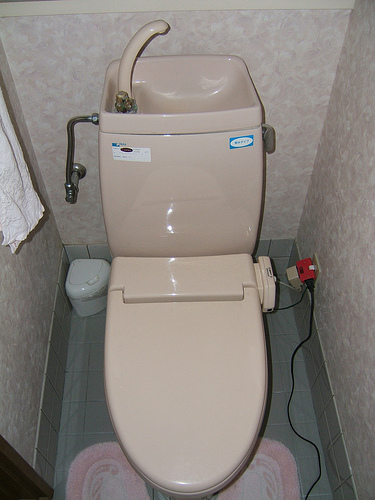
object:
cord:
[286, 284, 322, 499]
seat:
[104, 252, 267, 498]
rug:
[64, 437, 302, 499]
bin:
[65, 258, 111, 318]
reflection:
[166, 207, 175, 233]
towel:
[0, 87, 46, 254]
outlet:
[306, 251, 323, 287]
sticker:
[112, 142, 152, 162]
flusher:
[263, 124, 275, 154]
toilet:
[97, 19, 278, 498]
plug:
[306, 280, 316, 293]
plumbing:
[64, 115, 99, 205]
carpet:
[65, 435, 303, 500]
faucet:
[111, 18, 171, 113]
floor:
[68, 320, 103, 438]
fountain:
[117, 18, 171, 113]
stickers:
[229, 134, 254, 149]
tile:
[304, 343, 353, 478]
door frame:
[0, 433, 54, 499]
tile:
[44, 373, 62, 431]